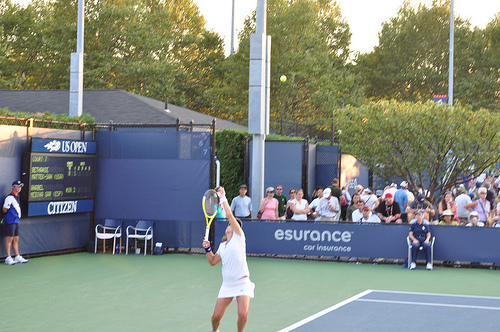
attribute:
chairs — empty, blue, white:
[95, 222, 154, 254]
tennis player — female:
[192, 183, 258, 331]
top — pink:
[261, 197, 281, 217]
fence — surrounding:
[8, 122, 209, 250]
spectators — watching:
[239, 186, 496, 223]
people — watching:
[251, 188, 377, 218]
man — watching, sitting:
[380, 194, 404, 220]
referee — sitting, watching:
[409, 208, 436, 268]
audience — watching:
[373, 171, 499, 219]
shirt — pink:
[264, 202, 277, 214]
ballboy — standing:
[4, 177, 36, 271]